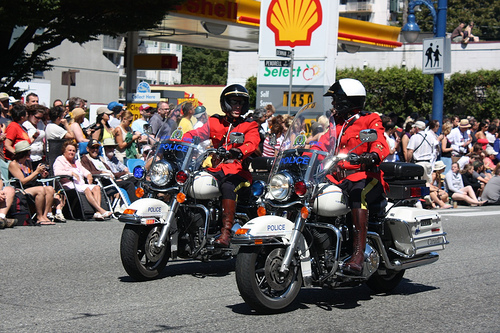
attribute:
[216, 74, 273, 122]
head — here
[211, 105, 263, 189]
person — here, wearing, dressed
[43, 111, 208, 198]
crowd — here, sitting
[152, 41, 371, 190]
policemen — wearing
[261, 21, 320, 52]
sign — white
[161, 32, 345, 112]
station — gass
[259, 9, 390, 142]
signs — behind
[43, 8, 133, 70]
tree — behind, shading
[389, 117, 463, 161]
people — sitting, many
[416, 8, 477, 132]
lamp — blue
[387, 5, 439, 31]
light — blue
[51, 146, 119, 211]
woman — sitting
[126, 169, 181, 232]
fender — white